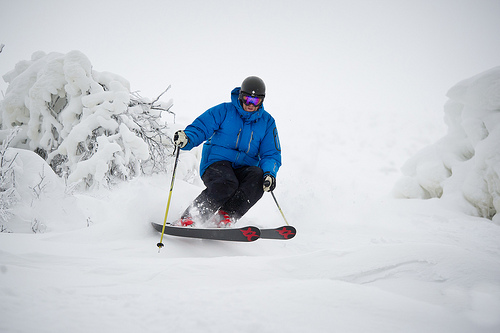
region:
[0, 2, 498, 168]
light in daytime sky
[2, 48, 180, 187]
snow cover on bush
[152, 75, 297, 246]
person on two skis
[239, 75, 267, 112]
helmet and goggles on head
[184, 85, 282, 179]
blue winter coat on skier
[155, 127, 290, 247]
gloved hands on poles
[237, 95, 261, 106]
The snow goggles the skier is wearing.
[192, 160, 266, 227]
The pants the skier is wearing.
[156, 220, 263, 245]
The left ski the skier is wearing.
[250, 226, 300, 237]
The tip of the right ski the skier is wearing.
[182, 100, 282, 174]
The blue coat the skier is wearing.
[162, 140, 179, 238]
The left ski pole in the skier's hand.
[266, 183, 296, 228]
The right ski pole the skier is holding.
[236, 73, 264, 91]
The helmet the skier is wearing.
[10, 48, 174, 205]
The snow covered bushes on the left.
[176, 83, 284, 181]
man wearing blue snow jacket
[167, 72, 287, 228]
man is skiing in thick snow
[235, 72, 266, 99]
man's helmet is black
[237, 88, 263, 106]
man wearing pair of goggles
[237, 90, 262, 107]
goggles are black framed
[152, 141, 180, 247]
ski pole is yellow and black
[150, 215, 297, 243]
pair of skis are black and red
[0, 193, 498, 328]
ground is covered with thick snow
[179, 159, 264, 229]
skier wearing black pants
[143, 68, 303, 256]
A person is skiing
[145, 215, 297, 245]
Two skis are black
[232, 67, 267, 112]
A black helmet on person's head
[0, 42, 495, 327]
A skiier on a ski slope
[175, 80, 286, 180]
A blue colored jacket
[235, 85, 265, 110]
A pair of goggles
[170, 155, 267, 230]
A pair of black ski pants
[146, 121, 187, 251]
A ski pole in a gloved hand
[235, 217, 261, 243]
Red markings on black ski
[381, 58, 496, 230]
A snow covered bush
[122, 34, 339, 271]
this is a man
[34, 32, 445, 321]
the man is skiing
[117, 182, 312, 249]
a set of skis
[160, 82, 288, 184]
a royal blue jacket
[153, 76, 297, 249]
person in a blue coat skiing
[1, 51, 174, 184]
snow covered bush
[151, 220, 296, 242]
black skis with red design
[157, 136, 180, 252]
yellow ski pole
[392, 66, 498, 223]
bush completely covered with snow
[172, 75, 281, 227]
person wearing blue coat and black pants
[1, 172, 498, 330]
snow covered ski slope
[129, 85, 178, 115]
limb sticking out of snow covered bush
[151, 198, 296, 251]
a pair of skis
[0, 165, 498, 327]
snow on the ground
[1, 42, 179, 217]
tree covered in snow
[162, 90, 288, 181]
person wearing a blue jacket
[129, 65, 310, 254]
a person is skiing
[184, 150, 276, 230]
black pair of pants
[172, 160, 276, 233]
person has knees bent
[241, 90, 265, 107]
a pair of goggles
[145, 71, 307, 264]
man in a blue colored jacket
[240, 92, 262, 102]
ski goggles on man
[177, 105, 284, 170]
blue colored jacket on the man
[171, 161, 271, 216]
black colored pants on the man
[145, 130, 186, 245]
right ski pole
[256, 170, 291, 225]
left ski pole